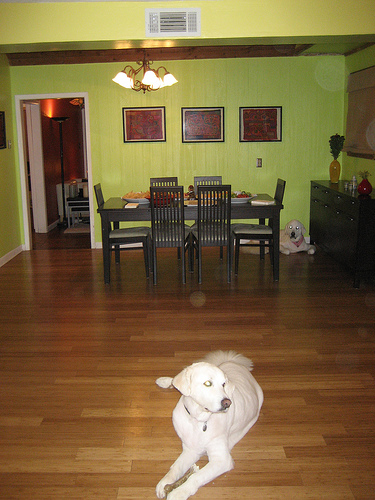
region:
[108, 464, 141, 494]
the floor is wooden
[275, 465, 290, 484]
the floor is wooden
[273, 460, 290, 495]
the floor is wooden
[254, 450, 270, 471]
the floor is wooden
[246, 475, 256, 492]
the floor is wooden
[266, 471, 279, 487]
the floor is wooden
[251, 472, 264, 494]
the floor is wooden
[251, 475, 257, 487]
the floor is wooden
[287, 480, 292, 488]
the floor is wooden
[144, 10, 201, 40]
gray vent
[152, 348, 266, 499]
large white dog on a hardwood floor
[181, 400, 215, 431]
tag hanging around a dog's neck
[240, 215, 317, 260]
a dog sitting behind a table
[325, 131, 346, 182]
green plant sticking out of a yellow vase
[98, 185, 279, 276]
plenty of food on top of a black table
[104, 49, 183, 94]
lights hanging from the ceiling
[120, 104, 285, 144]
three pieces of art hanging on the wall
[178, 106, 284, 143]
two pieces of art hanging from the wall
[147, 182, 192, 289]
black chair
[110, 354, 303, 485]
a yellow lab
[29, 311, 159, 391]
a brown wooden floor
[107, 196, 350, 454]
two dogs on the floor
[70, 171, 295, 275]
a dinning room table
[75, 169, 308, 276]
six dinner chairs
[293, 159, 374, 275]
a dark wooden hutch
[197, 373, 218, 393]
a dog's eye reflecting light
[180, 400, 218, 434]
a dog's collar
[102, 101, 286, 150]
three matching pictures in black frames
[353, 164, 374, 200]
a red flower vase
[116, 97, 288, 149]
three pictures hung on the wall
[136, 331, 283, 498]
dog with a chewed bone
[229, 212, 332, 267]
dog wearing a bandana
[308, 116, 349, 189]
yellow vase on the counter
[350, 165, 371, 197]
red vase on the counter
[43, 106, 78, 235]
black halogen floor lamp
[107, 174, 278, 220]
food is on the table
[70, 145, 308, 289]
six chairs at the table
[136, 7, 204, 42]
white metal vent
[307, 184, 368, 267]
dark brown kitchen cabinets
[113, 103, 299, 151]
A set of three framed paintings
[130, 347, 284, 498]
A yellow dog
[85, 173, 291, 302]
A dining room table and chairs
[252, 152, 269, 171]
A lightswitch on a wall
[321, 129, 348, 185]
A yellow vase with flowers in it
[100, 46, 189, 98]
A ceiling lamp, turned on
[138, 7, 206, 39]
A heating vent in a wall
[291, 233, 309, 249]
A pink bandana on a dog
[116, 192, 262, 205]
a delicious meal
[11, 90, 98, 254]
A doorway